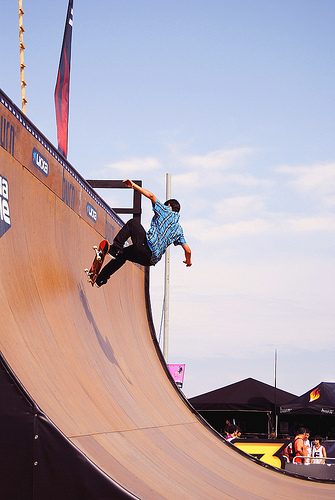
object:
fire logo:
[308, 387, 320, 402]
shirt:
[146, 198, 186, 267]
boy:
[83, 178, 192, 289]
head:
[164, 199, 180, 214]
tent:
[184, 378, 300, 444]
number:
[232, 441, 285, 470]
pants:
[97, 219, 152, 288]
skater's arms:
[132, 183, 161, 209]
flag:
[53, 1, 73, 161]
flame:
[54, 46, 68, 155]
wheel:
[93, 245, 97, 250]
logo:
[86, 201, 97, 223]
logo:
[32, 146, 49, 176]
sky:
[190, 83, 311, 169]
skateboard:
[84, 239, 109, 287]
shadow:
[77, 281, 133, 385]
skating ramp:
[0, 87, 334, 498]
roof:
[188, 375, 299, 408]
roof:
[279, 381, 334, 414]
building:
[183, 376, 335, 444]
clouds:
[276, 157, 335, 197]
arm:
[177, 226, 190, 261]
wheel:
[86, 278, 91, 283]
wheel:
[84, 267, 89, 272]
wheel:
[97, 256, 101, 261]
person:
[293, 427, 309, 465]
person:
[311, 436, 327, 464]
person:
[304, 429, 312, 466]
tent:
[279, 381, 335, 437]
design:
[91, 260, 100, 271]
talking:
[293, 428, 327, 466]